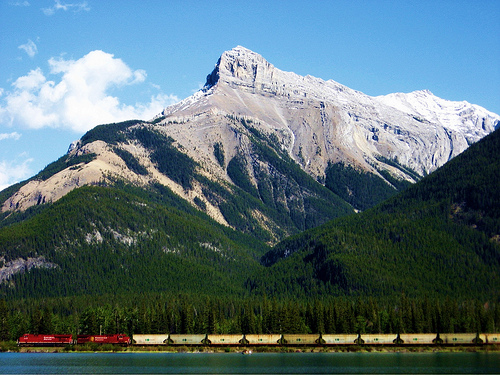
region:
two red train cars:
[7, 330, 128, 354]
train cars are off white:
[129, 328, 498, 349]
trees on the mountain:
[274, 238, 497, 327]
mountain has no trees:
[168, 27, 481, 152]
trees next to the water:
[13, 347, 498, 360]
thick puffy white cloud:
[53, 46, 160, 140]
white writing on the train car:
[40, 330, 60, 345]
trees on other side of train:
[20, 305, 497, 339]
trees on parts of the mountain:
[94, 128, 232, 239]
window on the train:
[18, 327, 37, 344]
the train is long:
[16, 323, 489, 353]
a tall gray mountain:
[135, 35, 477, 196]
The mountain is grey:
[144, 32, 496, 190]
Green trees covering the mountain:
[8, 126, 493, 334]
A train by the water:
[8, 324, 493, 353]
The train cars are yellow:
[130, 329, 492, 351]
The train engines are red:
[8, 327, 132, 349]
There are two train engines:
[13, 325, 133, 349]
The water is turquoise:
[58, 353, 470, 372]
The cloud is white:
[10, 37, 156, 144]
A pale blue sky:
[320, 6, 476, 79]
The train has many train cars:
[15, 324, 492, 358]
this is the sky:
[317, 13, 399, 58]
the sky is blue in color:
[331, 18, 407, 63]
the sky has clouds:
[11, 10, 143, 117]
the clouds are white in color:
[54, 61, 116, 114]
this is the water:
[91, 350, 174, 371]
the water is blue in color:
[175, 355, 222, 370]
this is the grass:
[166, 275, 344, 322]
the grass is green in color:
[198, 265, 234, 281]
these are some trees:
[202, 297, 302, 320]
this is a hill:
[214, 52, 361, 213]